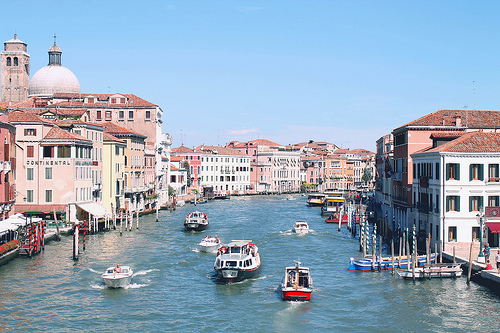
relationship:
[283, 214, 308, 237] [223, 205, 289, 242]
boat in water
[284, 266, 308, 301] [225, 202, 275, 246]
boat in water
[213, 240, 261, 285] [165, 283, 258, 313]
boat in water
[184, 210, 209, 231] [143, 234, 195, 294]
boat in water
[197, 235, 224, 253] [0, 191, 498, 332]
boat in water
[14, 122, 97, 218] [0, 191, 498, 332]
building near water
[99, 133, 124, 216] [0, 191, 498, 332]
building near water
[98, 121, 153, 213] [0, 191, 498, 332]
building near water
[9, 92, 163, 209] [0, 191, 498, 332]
building near water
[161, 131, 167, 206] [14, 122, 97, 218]
building near building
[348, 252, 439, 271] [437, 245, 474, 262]
boat by dock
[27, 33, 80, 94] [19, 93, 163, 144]
dome on building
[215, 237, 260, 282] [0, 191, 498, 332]
boat in water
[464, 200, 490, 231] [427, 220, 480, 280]
person on deck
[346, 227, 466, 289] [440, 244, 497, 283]
boats at dock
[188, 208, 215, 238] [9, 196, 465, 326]
boat in water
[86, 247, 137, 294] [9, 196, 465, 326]
boat in water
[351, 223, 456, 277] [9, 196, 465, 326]
boat in water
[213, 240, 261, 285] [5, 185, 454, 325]
boat in water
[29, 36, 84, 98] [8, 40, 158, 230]
dome on building